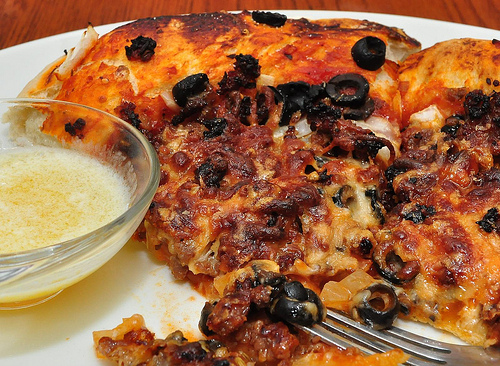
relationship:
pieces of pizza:
[104, 47, 432, 272] [44, 13, 441, 362]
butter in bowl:
[4, 144, 90, 221] [0, 111, 167, 265]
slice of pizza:
[77, 24, 354, 256] [44, 13, 441, 362]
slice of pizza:
[400, 19, 485, 299] [44, 13, 441, 362]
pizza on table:
[44, 13, 441, 362] [6, 16, 498, 328]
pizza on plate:
[44, 13, 441, 362] [22, 23, 479, 360]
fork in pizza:
[309, 285, 460, 351] [44, 13, 441, 362]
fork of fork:
[290, 292, 481, 364] [309, 285, 460, 351]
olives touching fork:
[271, 280, 324, 332] [309, 285, 460, 351]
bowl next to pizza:
[0, 111, 167, 265] [44, 13, 441, 362]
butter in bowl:
[4, 155, 89, 235] [0, 111, 167, 265]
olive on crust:
[357, 41, 397, 71] [101, 8, 390, 83]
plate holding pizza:
[22, 23, 479, 360] [44, 13, 441, 362]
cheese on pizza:
[190, 161, 321, 255] [44, 13, 441, 362]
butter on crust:
[4, 155, 89, 235] [101, 8, 390, 83]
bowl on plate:
[0, 111, 167, 265] [22, 23, 479, 360]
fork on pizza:
[309, 285, 460, 351] [44, 13, 441, 362]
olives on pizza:
[271, 280, 324, 332] [44, 13, 441, 362]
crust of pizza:
[101, 8, 390, 83] [44, 13, 441, 362]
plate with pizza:
[22, 23, 479, 360] [44, 13, 441, 362]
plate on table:
[22, 23, 479, 360] [6, 16, 498, 328]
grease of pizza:
[128, 278, 197, 325] [44, 13, 441, 362]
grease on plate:
[128, 278, 197, 325] [22, 23, 479, 360]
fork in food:
[309, 285, 460, 351] [25, 14, 448, 332]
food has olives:
[25, 14, 448, 332] [271, 280, 324, 332]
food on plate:
[25, 14, 448, 332] [22, 23, 479, 360]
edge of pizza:
[82, 22, 436, 116] [44, 13, 441, 362]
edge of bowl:
[122, 112, 165, 219] [0, 111, 167, 265]